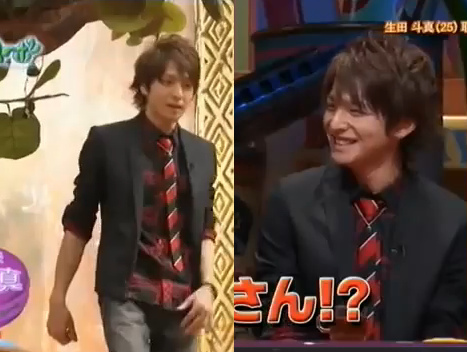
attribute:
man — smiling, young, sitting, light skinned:
[263, 35, 456, 335]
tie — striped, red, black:
[152, 130, 207, 272]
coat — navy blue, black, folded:
[72, 103, 222, 308]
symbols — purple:
[1, 246, 40, 331]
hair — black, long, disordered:
[314, 34, 438, 141]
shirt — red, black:
[118, 118, 196, 310]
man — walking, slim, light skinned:
[79, 35, 226, 349]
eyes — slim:
[160, 76, 198, 89]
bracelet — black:
[198, 275, 221, 298]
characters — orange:
[383, 18, 465, 36]